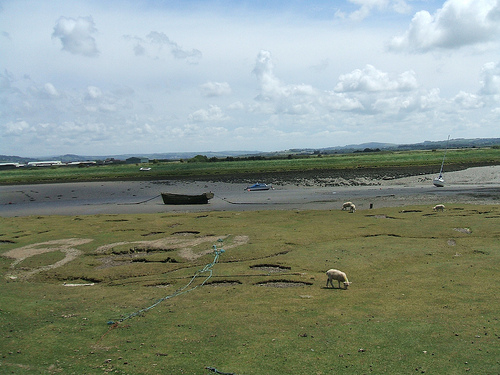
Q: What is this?
A: Pasture land.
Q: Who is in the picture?
A: No one.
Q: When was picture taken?
A: During daylight.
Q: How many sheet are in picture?
A: Three.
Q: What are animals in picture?
A: Sheep.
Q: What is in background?
A: Trees.